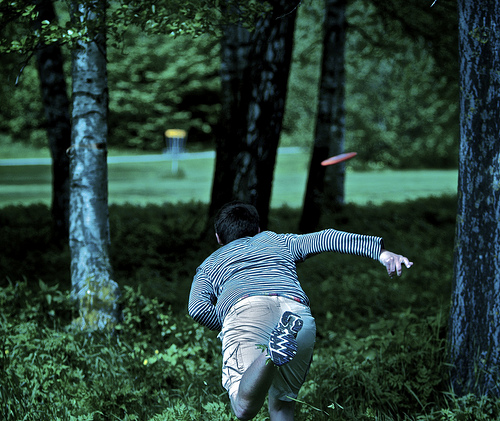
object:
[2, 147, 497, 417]
ground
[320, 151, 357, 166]
frisbee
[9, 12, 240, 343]
tree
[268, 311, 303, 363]
shoe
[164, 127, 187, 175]
disc gulf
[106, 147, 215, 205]
field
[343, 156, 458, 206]
field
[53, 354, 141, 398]
plants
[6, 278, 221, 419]
leaves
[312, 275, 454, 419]
leaves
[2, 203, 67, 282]
leaves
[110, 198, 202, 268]
leaves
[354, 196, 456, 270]
leaves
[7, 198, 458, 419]
ground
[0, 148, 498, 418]
field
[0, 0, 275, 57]
leaves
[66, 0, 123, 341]
tree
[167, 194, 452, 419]
man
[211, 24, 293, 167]
trunks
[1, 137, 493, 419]
grass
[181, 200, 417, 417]
man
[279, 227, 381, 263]
arm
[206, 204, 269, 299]
person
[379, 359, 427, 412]
patch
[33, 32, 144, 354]
tree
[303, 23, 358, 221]
tree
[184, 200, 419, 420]
person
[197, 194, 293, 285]
man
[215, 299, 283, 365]
shorts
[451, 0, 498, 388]
tree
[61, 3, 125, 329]
tree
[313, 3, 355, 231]
tree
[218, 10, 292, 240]
tree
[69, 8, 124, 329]
trunk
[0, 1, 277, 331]
tree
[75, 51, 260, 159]
sky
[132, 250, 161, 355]
plants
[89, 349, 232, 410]
ground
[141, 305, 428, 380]
ground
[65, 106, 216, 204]
air